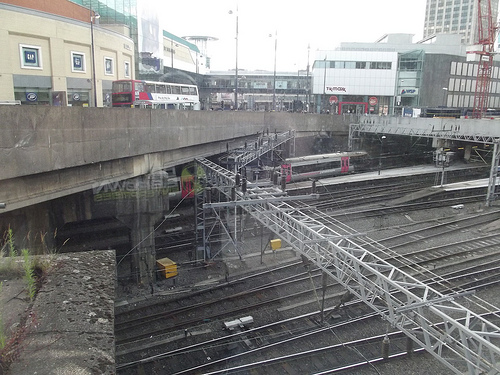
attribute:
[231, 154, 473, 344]
truss — metal, metallic, bridged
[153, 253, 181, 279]
box — yellow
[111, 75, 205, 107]
bus — double, white red, blue, present, red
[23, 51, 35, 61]
sign — blue, present, traffic, white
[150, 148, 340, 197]
train — tracked, red, white, present, black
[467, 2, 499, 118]
crane — red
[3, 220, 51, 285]
weeds — growing, small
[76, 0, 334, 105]
lamps — large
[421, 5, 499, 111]
building — white, high rise, taller, curved, windowed, commercial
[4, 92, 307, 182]
base — concrete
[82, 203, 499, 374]
tracks — railroad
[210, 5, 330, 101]
poles — rowed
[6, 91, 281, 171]
bridge — supported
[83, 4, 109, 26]
lights — along